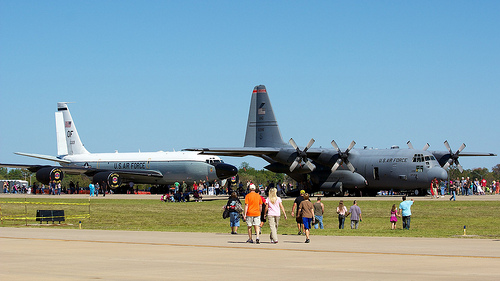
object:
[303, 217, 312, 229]
shorts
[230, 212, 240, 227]
shorts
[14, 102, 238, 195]
airplane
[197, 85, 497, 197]
airplane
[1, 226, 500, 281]
tarmac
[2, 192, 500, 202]
tarmac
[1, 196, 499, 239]
grass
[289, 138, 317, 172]
propeller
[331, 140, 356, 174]
propeller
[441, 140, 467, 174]
propeller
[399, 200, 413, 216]
t-shirt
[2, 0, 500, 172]
sky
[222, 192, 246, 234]
person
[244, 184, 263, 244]
person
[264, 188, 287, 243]
person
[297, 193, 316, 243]
person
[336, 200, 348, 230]
person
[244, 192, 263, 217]
t-shirt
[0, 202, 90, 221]
caution tape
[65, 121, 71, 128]
flag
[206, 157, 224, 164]
cockpit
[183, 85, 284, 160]
tail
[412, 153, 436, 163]
cockpit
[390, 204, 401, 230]
girl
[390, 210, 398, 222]
dress